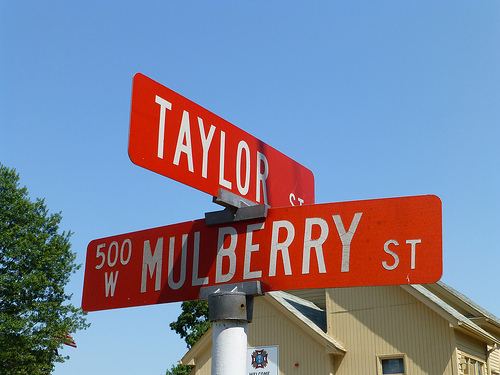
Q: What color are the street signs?
A: Red.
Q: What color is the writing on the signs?
A: White.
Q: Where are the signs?
A: On the pole.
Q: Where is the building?
A: Behind pole.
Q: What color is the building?
A: Yellow.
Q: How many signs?
A: Two.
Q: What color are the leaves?
A: Green.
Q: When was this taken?
A: During the day.